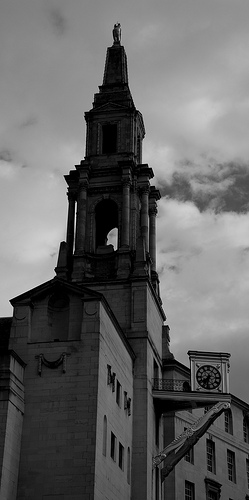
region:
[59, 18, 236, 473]
a clock is on the side of a tower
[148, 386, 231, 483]
the platform is connected by two carved supports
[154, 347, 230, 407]
a black fence is on the platform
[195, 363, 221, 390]
the clock has a white face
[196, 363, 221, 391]
the hands and roman numerals on the clock are black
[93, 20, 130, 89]
the cupola of the tower has a statue on top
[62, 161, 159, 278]
columns surround the base of the tower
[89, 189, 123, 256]
open arches are at the base of the tower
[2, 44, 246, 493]
the building is made of stone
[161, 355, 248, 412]
the building has parapets on the top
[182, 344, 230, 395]
A clock on side of the building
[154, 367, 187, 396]
A balcony on the building.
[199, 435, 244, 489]
Windows on the building.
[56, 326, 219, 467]
Photo is black and white.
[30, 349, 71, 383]
The building has an M on it.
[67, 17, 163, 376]
The building is tall.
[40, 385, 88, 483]
The building is made out of brick.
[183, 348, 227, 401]
The clock has roman numbers.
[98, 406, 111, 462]
The window is shaped like an arch.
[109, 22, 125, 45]
An object on top of the tower.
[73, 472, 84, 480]
a brick on a wall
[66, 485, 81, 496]
a brick on a wall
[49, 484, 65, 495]
a brick on a wall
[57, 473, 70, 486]
a brick on a wall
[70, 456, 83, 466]
a brick on a wall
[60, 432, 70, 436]
a brick on a wall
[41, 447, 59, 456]
a brick on a wall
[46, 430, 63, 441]
a brick on a wall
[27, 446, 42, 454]
a brick on a wall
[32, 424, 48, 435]
a brick on a wall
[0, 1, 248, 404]
The sky.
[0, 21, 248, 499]
An old building.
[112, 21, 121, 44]
A statue on top of the old building.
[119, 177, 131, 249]
A column on the old building.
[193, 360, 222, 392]
The face of a clock on an old building.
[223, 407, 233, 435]
A window on an old building.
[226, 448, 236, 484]
A window on an old building.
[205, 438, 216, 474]
A window on an old building.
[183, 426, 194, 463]
A window on an old building.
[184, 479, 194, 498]
A window on an old building.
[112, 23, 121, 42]
A statue on top of a building.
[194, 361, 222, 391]
A clock face on an old building.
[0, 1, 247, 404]
The sky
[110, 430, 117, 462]
A window on an old building.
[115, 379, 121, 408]
A window on an old building.